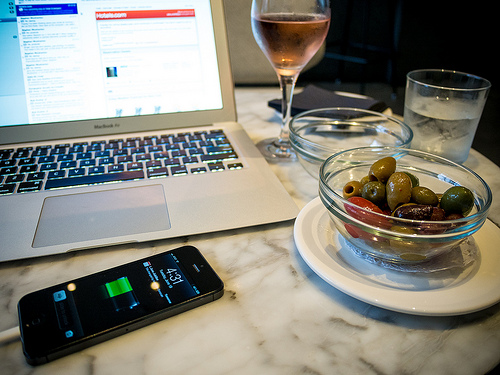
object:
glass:
[251, 0, 332, 169]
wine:
[251, 13, 331, 68]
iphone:
[12, 245, 224, 366]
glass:
[401, 69, 491, 165]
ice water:
[404, 100, 478, 157]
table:
[0, 247, 458, 375]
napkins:
[268, 84, 387, 121]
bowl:
[318, 146, 492, 264]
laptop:
[0, 0, 302, 263]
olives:
[386, 172, 413, 210]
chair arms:
[324, 47, 370, 95]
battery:
[105, 276, 140, 312]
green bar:
[104, 276, 131, 298]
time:
[166, 268, 185, 285]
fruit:
[369, 156, 396, 183]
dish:
[291, 188, 499, 317]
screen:
[39, 251, 200, 346]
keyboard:
[1, 128, 246, 196]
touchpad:
[31, 183, 171, 248]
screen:
[1, 0, 225, 130]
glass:
[309, 112, 355, 136]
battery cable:
[0, 324, 20, 345]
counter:
[235, 236, 315, 374]